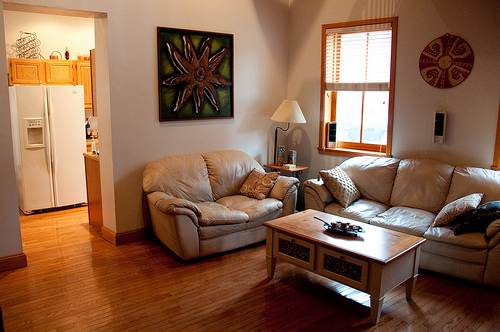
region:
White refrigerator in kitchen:
[0, 63, 100, 221]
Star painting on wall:
[144, 9, 237, 129]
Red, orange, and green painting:
[136, 18, 257, 135]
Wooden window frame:
[309, 10, 411, 165]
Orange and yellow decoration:
[410, 27, 483, 99]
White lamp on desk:
[254, 89, 314, 172]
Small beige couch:
[141, 144, 298, 264]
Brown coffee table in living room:
[245, 190, 438, 321]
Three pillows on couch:
[309, 151, 498, 264]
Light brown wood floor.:
[20, 244, 110, 330]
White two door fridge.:
[16, 78, 91, 222]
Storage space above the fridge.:
[7, 53, 90, 88]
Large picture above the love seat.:
[147, 28, 242, 120]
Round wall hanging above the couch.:
[411, 30, 477, 95]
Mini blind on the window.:
[314, 23, 390, 101]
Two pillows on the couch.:
[433, 195, 495, 235]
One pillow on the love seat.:
[235, 160, 280, 204]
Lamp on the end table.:
[256, 92, 306, 168]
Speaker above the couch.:
[421, 107, 455, 144]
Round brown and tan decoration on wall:
[415, 33, 477, 90]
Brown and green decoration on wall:
[160, 28, 238, 123]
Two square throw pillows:
[435, 188, 492, 237]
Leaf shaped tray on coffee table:
[308, 211, 366, 241]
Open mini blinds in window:
[324, 23, 394, 93]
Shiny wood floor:
[20, 260, 166, 326]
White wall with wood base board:
[105, 24, 134, 246]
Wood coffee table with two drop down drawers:
[267, 226, 369, 280]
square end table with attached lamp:
[265, 97, 307, 172]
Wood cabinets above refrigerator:
[7, 59, 77, 84]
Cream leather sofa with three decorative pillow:
[298, 146, 496, 208]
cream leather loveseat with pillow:
[138, 136, 283, 248]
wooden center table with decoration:
[271, 196, 413, 309]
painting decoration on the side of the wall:
[142, 25, 242, 128]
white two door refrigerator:
[10, 83, 91, 211]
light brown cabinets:
[6, 55, 89, 85]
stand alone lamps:
[265, 82, 308, 168]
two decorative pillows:
[433, 190, 494, 241]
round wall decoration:
[413, 25, 478, 101]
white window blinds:
[316, 17, 396, 155]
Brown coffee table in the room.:
[257, 204, 424, 323]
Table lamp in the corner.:
[262, 93, 306, 172]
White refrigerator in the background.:
[13, 85, 88, 215]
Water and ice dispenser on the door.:
[21, 111, 46, 151]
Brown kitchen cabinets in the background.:
[7, 54, 94, 109]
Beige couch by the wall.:
[300, 150, 498, 280]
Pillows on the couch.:
[432, 188, 499, 237]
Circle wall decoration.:
[415, 30, 477, 92]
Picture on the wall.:
[152, 20, 238, 125]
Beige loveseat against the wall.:
[144, 150, 296, 260]